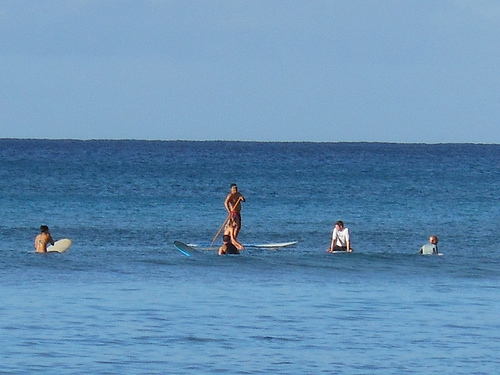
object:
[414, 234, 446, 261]
person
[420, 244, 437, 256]
shirt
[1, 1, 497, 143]
sky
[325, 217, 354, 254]
man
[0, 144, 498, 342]
ocean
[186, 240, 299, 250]
board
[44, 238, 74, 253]
surfboard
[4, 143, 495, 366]
water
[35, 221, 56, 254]
person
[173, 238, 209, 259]
surfboard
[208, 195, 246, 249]
paddle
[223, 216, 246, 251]
woman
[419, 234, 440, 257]
man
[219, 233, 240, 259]
man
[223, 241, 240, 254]
top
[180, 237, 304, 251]
surfboard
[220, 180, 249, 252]
man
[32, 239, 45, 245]
bikini top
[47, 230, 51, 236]
hand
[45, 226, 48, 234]
face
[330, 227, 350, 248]
shirt